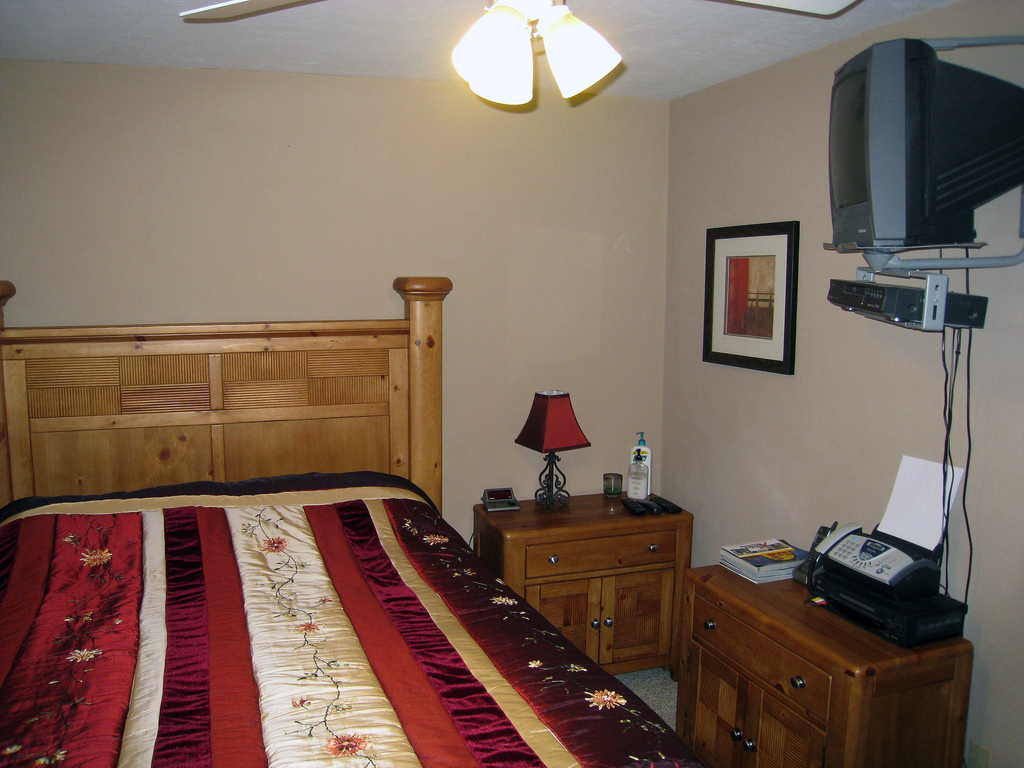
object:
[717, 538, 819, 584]
books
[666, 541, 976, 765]
cabinet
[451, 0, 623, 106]
light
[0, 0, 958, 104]
ceiling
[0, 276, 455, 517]
headboard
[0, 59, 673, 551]
wall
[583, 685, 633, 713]
flower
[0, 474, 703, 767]
bed spread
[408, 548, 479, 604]
flowers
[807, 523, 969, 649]
printer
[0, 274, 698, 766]
bed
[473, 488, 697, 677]
table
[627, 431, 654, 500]
bottles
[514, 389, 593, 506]
lamp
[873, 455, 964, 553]
printer paper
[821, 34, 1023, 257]
television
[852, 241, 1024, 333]
stand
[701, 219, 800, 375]
picture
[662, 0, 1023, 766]
wall